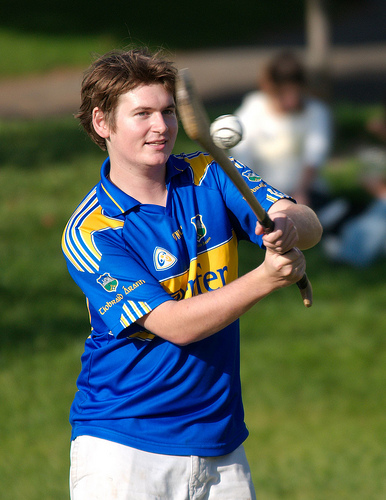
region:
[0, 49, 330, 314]
the young man is swinging the stick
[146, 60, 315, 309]
the stick is going to hit the ball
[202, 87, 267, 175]
the ball is in the air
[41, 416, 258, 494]
the pants are white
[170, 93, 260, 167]
the ball is white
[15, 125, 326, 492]
the shirt is short sleeves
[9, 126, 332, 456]
the shirt is blue, yellow, and white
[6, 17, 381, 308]
the background is blurry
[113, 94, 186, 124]
the eyes are open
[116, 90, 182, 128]
the eyes are blue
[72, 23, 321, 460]
A boy wearing a jersey.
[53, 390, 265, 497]
The shorts are white.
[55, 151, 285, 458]
The jersey is blue and yellow.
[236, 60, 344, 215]
The woman is wearing a white shirt.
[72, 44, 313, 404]
A boy playing cricket.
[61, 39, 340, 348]
A boy hitting a cricket ball.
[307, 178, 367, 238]
A black and white bag.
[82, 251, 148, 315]
A school emblem.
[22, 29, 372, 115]
A pathway.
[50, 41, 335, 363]
The boy is playing a game.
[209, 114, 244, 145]
The ball is white.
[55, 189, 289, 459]
The shirt is blue.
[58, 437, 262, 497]
His pants are white.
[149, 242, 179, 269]
The logo is white and yellow.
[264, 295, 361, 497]
The grass is green.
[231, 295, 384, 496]
The grass is lush.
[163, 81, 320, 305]
The stick is brown.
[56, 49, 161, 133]
His hair is brown.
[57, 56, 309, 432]
He is playing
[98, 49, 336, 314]
He is swinging .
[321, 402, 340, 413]
part of a grass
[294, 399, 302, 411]
part of the lawn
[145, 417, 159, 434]
part of a shirt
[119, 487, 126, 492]
part of a short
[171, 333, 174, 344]
part of an elbow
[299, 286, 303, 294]
part of a racket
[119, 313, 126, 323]
part of a shirt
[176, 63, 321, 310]
Man hitting ball with mallet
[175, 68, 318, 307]
Mallet in man's hands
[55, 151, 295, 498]
Yellow and blue jersey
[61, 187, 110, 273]
Yellow and white stripes on shoulder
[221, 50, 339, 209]
Person in background wearing white shirt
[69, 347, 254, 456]
Wrinkles on bottom of man's shirt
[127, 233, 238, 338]
Blue lettering on yellow background of shirt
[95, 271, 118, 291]
Patch on sleeve of shirt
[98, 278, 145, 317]
Yellow lettering on sleeve of blue shirt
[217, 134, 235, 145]
Writing on side of ball